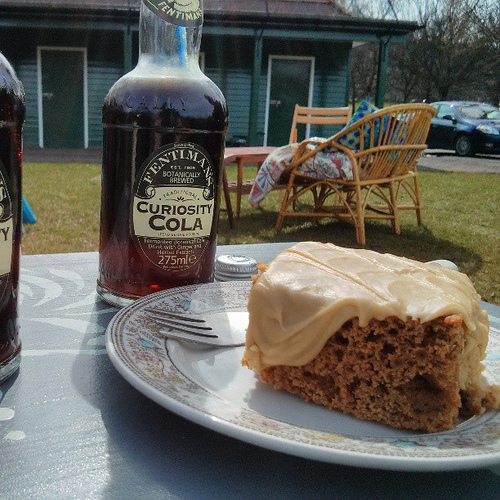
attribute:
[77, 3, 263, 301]
bottle — drink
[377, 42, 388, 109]
support pole — green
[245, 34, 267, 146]
support pole — green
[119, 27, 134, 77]
support pole — green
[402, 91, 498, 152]
car — parked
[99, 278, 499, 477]
plate — white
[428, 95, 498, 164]
car — dark colored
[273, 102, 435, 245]
furniture — wicker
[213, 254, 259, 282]
bottlecap — silver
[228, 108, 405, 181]
white blanket — blue, pink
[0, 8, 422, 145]
building — greenish blue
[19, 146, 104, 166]
porch — long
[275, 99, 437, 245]
bench — wicker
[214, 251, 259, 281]
cap — silver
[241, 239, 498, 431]
carrot cake — a piece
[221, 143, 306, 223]
picnic table — with graphics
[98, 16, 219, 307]
soda bottle — glass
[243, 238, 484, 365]
icing — white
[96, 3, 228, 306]
bottle — Curiosity Cola